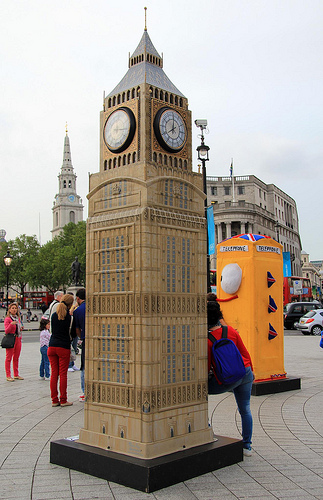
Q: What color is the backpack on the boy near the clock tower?
A: Blue.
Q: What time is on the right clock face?
A: 8 o'clock.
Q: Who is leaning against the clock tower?
A: The woman with a red shirt.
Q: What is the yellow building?
A: A replica of a telephone booth.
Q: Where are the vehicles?
A: In the roundabout.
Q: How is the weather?
A: Cloudy.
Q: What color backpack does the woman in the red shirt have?
A: Blue.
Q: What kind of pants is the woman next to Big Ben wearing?
A: Skinny jeans.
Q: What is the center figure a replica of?
A: Big Ben.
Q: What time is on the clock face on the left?
A: 11:15.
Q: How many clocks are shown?
A: 2.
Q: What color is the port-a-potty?
A: Orange.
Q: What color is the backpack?
A: Blue.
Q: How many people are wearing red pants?
A: 1.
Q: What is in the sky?
A: Clouds.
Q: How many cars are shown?
A: 2.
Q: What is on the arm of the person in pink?
A: Purse strap.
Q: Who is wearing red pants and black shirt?
A: A female.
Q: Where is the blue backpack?
A: On person leaning against clock tower.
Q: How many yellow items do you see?
A: 1.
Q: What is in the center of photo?
A: Clock tower.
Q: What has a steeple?
A: Church in background.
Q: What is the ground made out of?
A: Stone.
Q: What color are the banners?
A: Blue.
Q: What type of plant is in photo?
A: Trees.